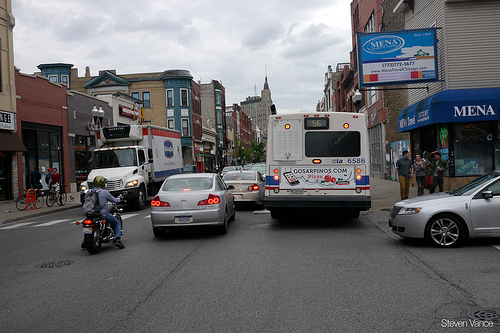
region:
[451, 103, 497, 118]
White letters on overhang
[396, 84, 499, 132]
Blue and white overhang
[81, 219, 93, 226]
Red tail light on motorcycle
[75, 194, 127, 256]
Motorcycle with red tail light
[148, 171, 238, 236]
Silver car on street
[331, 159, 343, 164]
Blue letters on bus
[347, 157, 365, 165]
Blue numbers on bus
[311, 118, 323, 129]
Green numbers on bus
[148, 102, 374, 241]
Silver car next to bus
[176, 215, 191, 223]
White plate on silver car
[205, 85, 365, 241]
a bus on the road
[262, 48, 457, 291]
a bus on the street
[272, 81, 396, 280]
a white bus on the road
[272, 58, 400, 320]
a white bus on the street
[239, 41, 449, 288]
a passenger bus on the road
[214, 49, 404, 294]
a passenger bus on the stove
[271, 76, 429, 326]
a white passenger bus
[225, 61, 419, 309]
a white passenger bus on the road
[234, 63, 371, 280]
a white passenger bus on the street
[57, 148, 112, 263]
a motorcycle on the road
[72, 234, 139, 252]
Man wearing shoes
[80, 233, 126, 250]
Man is wearing shoes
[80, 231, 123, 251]
Man wearing black shoes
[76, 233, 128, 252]
Man is wearing black shoes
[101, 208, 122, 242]
Man wearing pants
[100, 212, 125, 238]
Man is wearing pants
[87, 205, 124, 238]
Man wearing blue pants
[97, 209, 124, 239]
Man is wearing blue pants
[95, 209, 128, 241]
Man wearing blue jeans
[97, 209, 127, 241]
Man is wearing blue jeans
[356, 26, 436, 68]
MENA can be read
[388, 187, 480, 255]
a silver chrome car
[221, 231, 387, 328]
pavement is grey clean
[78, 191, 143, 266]
man on motorcycle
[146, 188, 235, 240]
2 red tail lights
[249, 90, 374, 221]
bus has many lights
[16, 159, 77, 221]
2 people on bikes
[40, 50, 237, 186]
large colorful building highrise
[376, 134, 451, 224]
a group of people walking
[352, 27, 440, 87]
advertisement sign on the side of building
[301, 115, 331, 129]
number 56 on the back of a bus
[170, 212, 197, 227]
licence plate on the back of silver car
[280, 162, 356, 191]
advertisement on back of bus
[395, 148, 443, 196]
people standing on street corner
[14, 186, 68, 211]
two bikes on the sidewalk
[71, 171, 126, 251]
person riding on a motorcycle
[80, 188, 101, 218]
person on motorcycle wearing backpack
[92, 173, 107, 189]
golden helmet of the motorcycle rider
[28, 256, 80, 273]
black man hole cove in the street